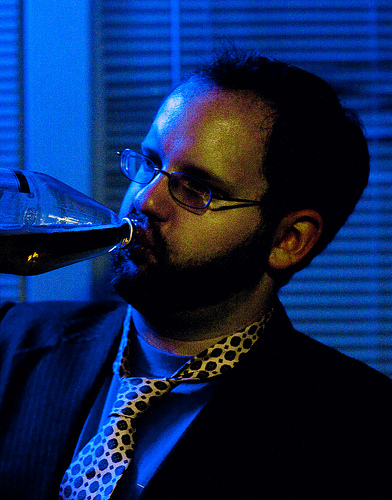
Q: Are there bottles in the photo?
A: Yes, there is a bottle.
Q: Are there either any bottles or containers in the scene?
A: Yes, there is a bottle.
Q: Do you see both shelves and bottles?
A: No, there is a bottle but no shelves.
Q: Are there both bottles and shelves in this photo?
A: No, there is a bottle but no shelves.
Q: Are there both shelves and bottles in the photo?
A: No, there is a bottle but no shelves.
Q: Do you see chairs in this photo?
A: No, there are no chairs.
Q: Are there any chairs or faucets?
A: No, there are no chairs or faucets.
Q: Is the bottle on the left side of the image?
A: Yes, the bottle is on the left of the image.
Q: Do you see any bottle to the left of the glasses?
A: Yes, there is a bottle to the left of the glasses.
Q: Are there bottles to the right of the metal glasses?
A: No, the bottle is to the left of the glasses.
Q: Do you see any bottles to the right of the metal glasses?
A: No, the bottle is to the left of the glasses.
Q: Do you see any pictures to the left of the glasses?
A: No, there is a bottle to the left of the glasses.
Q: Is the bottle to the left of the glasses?
A: Yes, the bottle is to the left of the glasses.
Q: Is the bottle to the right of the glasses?
A: No, the bottle is to the left of the glasses.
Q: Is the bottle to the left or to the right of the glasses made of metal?
A: The bottle is to the left of the glasses.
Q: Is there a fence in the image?
A: No, there are no fences.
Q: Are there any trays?
A: No, there are no trays.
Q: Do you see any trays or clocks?
A: No, there are no trays or clocks.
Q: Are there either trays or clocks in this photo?
A: No, there are no trays or clocks.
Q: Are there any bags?
A: No, there are no bags.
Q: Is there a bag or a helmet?
A: No, there are no bags or helmets.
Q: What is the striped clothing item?
A: The clothing item is a jacket.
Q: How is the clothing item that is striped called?
A: The clothing item is a jacket.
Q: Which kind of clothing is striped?
A: The clothing is a jacket.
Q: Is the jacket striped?
A: Yes, the jacket is striped.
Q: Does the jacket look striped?
A: Yes, the jacket is striped.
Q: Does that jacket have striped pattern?
A: Yes, the jacket is striped.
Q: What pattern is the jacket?
A: The jacket is striped.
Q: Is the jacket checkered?
A: No, the jacket is striped.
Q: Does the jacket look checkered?
A: No, the jacket is striped.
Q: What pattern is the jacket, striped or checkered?
A: The jacket is striped.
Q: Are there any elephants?
A: No, there are no elephants.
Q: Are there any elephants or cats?
A: No, there are no elephants or cats.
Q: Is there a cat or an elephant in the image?
A: No, there are no elephants or cats.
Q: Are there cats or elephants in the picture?
A: No, there are no elephants or cats.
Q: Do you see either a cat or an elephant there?
A: No, there are no elephants or cats.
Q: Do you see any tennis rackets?
A: No, there are no tennis rackets.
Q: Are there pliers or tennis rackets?
A: No, there are no tennis rackets or pliers.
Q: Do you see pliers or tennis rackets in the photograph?
A: No, there are no tennis rackets or pliers.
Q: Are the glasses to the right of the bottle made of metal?
A: Yes, the glasses are made of metal.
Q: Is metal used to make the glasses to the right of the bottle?
A: Yes, the glasses are made of metal.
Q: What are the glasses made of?
A: The glasses are made of metal.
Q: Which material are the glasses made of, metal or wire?
A: The glasses are made of metal.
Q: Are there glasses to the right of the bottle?
A: Yes, there are glasses to the right of the bottle.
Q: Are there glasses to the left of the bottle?
A: No, the glasses are to the right of the bottle.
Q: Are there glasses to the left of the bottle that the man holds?
A: No, the glasses are to the right of the bottle.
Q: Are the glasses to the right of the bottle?
A: Yes, the glasses are to the right of the bottle.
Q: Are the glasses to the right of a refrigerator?
A: No, the glasses are to the right of the bottle.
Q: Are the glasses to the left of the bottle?
A: No, the glasses are to the right of the bottle.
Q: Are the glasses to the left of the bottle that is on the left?
A: No, the glasses are to the right of the bottle.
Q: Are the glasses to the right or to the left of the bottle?
A: The glasses are to the right of the bottle.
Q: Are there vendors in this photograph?
A: No, there are no vendors.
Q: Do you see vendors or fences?
A: No, there are no vendors or fences.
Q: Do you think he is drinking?
A: Yes, the man is drinking.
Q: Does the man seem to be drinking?
A: Yes, the man is drinking.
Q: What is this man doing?
A: The man is drinking.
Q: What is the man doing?
A: The man is drinking.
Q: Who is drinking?
A: The man is drinking.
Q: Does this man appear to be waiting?
A: No, the man is drinking.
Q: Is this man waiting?
A: No, the man is drinking.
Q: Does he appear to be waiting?
A: No, the man is drinking.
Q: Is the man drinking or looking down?
A: The man is drinking.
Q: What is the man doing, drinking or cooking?
A: The man is drinking.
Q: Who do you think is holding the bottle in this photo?
A: The man is holding the bottle.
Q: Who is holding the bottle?
A: The man is holding the bottle.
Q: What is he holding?
A: The man is holding the bottle.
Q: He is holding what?
A: The man is holding the bottle.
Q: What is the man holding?
A: The man is holding the bottle.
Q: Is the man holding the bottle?
A: Yes, the man is holding the bottle.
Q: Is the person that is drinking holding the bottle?
A: Yes, the man is holding the bottle.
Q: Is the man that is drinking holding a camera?
A: No, the man is holding the bottle.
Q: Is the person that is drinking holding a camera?
A: No, the man is holding the bottle.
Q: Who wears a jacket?
A: The man wears a jacket.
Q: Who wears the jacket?
A: The man wears a jacket.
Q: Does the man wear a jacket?
A: Yes, the man wears a jacket.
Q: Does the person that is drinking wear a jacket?
A: Yes, the man wears a jacket.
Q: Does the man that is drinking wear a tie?
A: No, the man wears a jacket.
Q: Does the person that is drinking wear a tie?
A: No, the man wears a jacket.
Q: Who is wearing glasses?
A: The man is wearing glasses.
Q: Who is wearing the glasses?
A: The man is wearing glasses.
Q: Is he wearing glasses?
A: Yes, the man is wearing glasses.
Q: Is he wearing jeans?
A: No, the man is wearing glasses.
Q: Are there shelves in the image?
A: No, there are no shelves.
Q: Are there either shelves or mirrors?
A: No, there are no shelves or mirrors.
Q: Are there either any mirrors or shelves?
A: No, there are no shelves or mirrors.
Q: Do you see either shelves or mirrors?
A: No, there are no shelves or mirrors.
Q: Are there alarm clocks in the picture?
A: No, there are no alarm clocks.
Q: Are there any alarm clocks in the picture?
A: No, there are no alarm clocks.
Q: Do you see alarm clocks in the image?
A: No, there are no alarm clocks.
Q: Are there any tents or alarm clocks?
A: No, there are no alarm clocks or tents.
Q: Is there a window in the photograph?
A: Yes, there is a window.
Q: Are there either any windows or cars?
A: Yes, there is a window.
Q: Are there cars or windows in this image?
A: Yes, there is a window.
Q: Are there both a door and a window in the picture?
A: No, there is a window but no doors.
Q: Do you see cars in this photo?
A: No, there are no cars.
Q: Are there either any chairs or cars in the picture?
A: No, there are no cars or chairs.